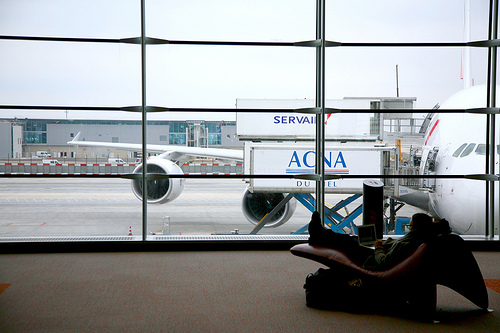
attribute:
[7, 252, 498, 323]
carpeting — gray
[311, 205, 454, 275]
person — reclining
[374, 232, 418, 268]
shirt — green